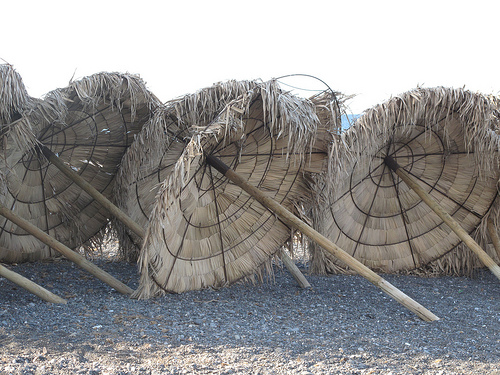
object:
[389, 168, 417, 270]
black support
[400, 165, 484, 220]
black support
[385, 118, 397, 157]
black support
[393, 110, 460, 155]
black support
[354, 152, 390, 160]
black support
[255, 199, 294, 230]
black support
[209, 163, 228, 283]
black support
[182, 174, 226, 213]
support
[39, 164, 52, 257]
support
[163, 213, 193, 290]
support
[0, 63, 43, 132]
umbrella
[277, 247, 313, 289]
pole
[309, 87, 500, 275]
tents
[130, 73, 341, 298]
tent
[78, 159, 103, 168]
holes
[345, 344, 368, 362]
rock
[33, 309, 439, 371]
ground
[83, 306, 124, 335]
dirt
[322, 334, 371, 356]
sand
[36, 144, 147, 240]
post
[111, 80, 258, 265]
umbrella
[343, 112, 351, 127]
ocean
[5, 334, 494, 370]
beach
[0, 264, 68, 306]
posts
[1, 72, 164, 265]
umbrellas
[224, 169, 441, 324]
board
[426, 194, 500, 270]
umbrella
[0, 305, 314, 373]
floor